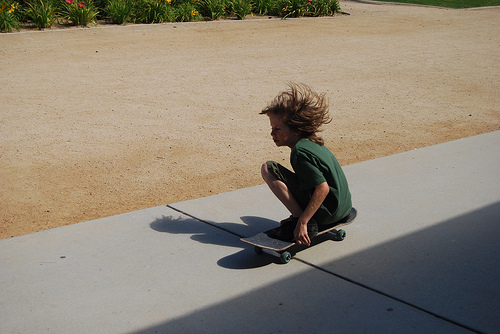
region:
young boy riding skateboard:
[239, 82, 358, 266]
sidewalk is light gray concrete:
[1, 128, 496, 330]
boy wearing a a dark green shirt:
[257, 82, 352, 247]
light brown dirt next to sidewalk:
[0, 3, 498, 332]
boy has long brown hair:
[258, 82, 355, 247]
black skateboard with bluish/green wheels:
[239, 205, 359, 263]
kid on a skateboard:
[256, 80, 353, 249]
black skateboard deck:
[241, 204, 359, 254]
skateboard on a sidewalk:
[236, 208, 360, 265]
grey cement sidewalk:
[0, 125, 499, 330]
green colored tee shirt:
[288, 137, 357, 224]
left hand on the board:
[292, 214, 312, 251]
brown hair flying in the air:
[258, 78, 335, 135]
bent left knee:
[257, 159, 286, 185]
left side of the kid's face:
[264, 108, 291, 151]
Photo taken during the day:
[11, 8, 491, 332]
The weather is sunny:
[9, 0, 496, 330]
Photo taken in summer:
[4, 10, 496, 327]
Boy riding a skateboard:
[242, 70, 353, 287]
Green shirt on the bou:
[279, 136, 357, 225]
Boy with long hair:
[223, 80, 380, 262]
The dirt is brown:
[9, 0, 496, 233]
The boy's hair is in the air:
[249, 80, 338, 138]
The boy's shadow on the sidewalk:
[145, 204, 305, 273]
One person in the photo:
[6, 1, 491, 326]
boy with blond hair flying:
[263, 85, 328, 138]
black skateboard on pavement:
[236, 200, 363, 267]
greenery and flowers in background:
[3, 4, 348, 33]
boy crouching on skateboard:
[258, 80, 361, 242]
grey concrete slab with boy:
[5, 125, 499, 323]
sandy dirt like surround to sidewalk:
[11, 0, 498, 231]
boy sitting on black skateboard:
[232, 76, 360, 265]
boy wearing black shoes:
[277, 218, 314, 233]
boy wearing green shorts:
[264, 163, 322, 231]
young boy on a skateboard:
[260, 81, 351, 246]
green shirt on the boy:
[291, 134, 353, 226]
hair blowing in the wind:
[261, 79, 333, 143]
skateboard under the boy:
[240, 203, 359, 262]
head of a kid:
[235, 84, 333, 159]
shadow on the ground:
[114, 176, 251, 273]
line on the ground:
[326, 263, 426, 326]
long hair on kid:
[259, 75, 346, 147]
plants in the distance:
[16, 0, 184, 48]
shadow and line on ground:
[141, 182, 231, 254]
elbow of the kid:
[303, 171, 345, 214]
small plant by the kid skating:
[23, 0, 51, 34]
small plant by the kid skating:
[0, 0, 22, 30]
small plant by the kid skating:
[62, 0, 98, 29]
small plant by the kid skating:
[100, 0, 132, 24]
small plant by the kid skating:
[136, 0, 163, 28]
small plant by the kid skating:
[155, 0, 182, 23]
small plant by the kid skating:
[197, 0, 225, 21]